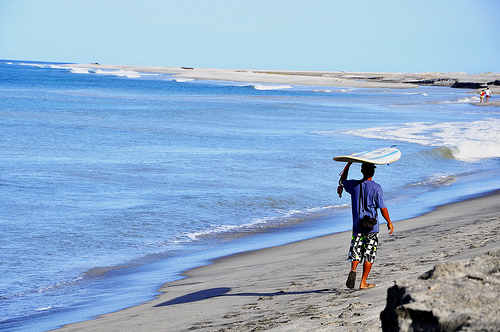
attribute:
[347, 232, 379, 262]
shorts — plaid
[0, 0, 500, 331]
water — blue, calm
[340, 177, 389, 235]
shirt — blue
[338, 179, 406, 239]
shirt — blue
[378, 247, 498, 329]
rock — Large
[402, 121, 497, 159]
foam — white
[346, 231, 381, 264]
boardshorts —  patterned 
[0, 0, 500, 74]
sky — blue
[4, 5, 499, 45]
sky — blue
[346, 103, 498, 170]
wave — White 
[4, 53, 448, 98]
wave — White 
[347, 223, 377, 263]
shorts — black, white, long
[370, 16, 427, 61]
sky — blue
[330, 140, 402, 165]
board — white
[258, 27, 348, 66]
clouds — white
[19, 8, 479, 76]
sky — blue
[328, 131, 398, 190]
stripes — blue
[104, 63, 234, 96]
clouds — white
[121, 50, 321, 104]
clouds — white